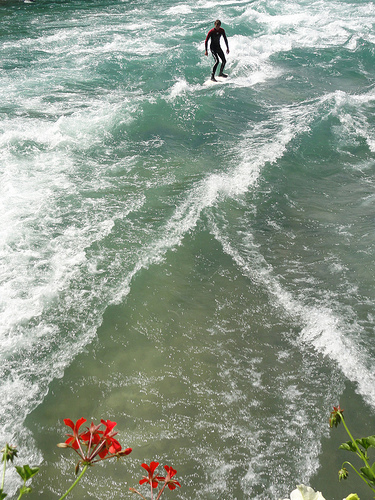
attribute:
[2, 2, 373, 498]
water — calm, flow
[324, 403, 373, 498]
plant — green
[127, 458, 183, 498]
plant — green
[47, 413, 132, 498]
plant — green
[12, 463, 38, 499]
plant — green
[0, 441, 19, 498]
plant — green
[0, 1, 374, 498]
waves — white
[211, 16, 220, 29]
hair — brown